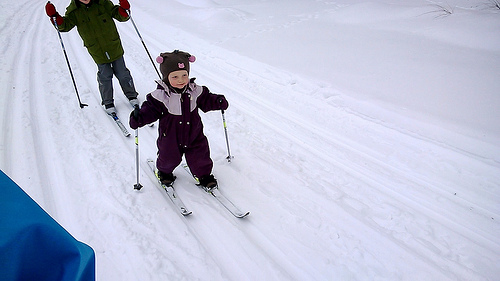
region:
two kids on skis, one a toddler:
[31, 0, 259, 235]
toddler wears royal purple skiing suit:
[115, 76, 237, 192]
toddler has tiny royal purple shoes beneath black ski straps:
[156, 167, 219, 189]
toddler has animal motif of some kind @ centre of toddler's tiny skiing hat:
[177, 60, 189, 70]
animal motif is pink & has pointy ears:
[175, 60, 187, 68]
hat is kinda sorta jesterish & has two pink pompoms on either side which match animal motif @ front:
[150, 51, 197, 66]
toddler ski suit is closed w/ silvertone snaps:
[148, 92, 214, 152]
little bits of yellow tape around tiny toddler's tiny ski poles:
[120, 96, 240, 196]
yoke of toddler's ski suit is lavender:
[149, 76, 204, 117]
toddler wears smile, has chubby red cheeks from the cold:
[166, 68, 192, 92]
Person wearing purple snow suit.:
[164, 110, 213, 190]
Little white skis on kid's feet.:
[112, 132, 279, 271]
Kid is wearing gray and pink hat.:
[152, 34, 209, 131]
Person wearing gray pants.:
[87, 91, 152, 111]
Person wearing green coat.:
[88, 15, 139, 113]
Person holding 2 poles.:
[46, 50, 208, 91]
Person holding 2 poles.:
[121, 109, 318, 194]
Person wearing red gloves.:
[34, 8, 69, 33]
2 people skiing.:
[68, 65, 250, 252]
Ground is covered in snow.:
[281, 179, 407, 274]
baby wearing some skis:
[122, 46, 254, 223]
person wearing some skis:
[29, 0, 162, 129]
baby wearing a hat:
[115, 42, 266, 232]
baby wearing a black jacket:
[130, 45, 247, 225]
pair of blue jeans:
[85, 45, 148, 109]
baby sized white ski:
[140, 153, 197, 221]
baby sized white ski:
[180, 156, 251, 220]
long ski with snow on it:
[97, 90, 133, 139]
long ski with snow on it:
[127, 102, 159, 128]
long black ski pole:
[46, 1, 89, 113]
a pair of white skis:
[133, 151, 262, 235]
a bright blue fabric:
[9, 207, 45, 253]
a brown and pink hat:
[155, 42, 203, 88]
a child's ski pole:
[212, 91, 244, 170]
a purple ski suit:
[118, 80, 247, 204]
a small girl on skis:
[123, 51, 282, 222]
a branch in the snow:
[423, 2, 465, 25]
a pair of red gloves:
[37, 0, 147, 24]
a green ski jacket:
[51, 2, 138, 67]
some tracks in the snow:
[79, 46, 439, 231]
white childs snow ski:
[145, 156, 192, 221]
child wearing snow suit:
[130, 53, 227, 192]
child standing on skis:
[130, 48, 230, 190]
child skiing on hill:
[128, 51, 223, 193]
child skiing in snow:
[131, 50, 225, 193]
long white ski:
[186, 163, 248, 223]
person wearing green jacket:
[42, 1, 142, 116]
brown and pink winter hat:
[156, 50, 193, 77]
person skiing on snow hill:
[45, 0, 145, 115]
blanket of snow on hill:
[1, 1, 498, 279]